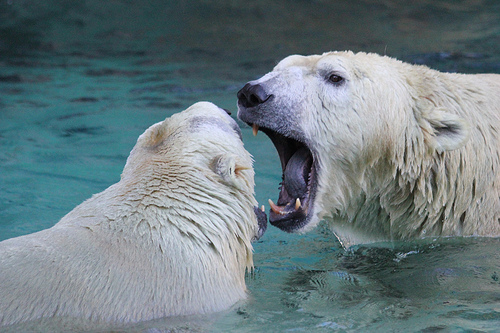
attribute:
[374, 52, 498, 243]
fur — wet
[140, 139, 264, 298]
fur — wet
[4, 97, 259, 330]
polar bear — large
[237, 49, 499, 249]
bear — in the picture, polar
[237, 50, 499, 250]
polar bear — large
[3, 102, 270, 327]
bear — in the picture, polar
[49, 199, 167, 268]
back — white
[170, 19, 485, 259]
bear — polar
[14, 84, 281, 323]
bear — polar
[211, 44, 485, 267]
bear — polar